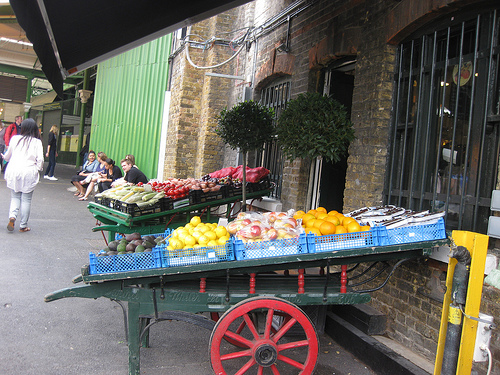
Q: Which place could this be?
A: It is a street.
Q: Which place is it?
A: It is a street.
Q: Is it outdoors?
A: Yes, it is outdoors.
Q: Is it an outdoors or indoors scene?
A: It is outdoors.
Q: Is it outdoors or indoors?
A: It is outdoors.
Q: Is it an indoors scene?
A: No, it is outdoors.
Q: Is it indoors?
A: No, it is outdoors.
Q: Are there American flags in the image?
A: No, there are no American flags.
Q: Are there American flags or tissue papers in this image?
A: No, there are no American flags or tissue papers.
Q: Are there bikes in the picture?
A: No, there are no bikes.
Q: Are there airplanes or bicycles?
A: No, there are no bicycles or airplanes.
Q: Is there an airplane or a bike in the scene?
A: No, there are no bikes or airplanes.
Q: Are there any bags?
A: No, there are no bags.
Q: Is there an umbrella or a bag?
A: No, there are no bags or umbrellas.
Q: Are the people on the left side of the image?
A: Yes, the people are on the left of the image.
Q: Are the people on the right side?
A: No, the people are on the left of the image.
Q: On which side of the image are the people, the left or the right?
A: The people are on the left of the image.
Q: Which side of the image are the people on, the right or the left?
A: The people are on the left of the image.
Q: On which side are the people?
A: The people are on the left of the image.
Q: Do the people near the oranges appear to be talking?
A: Yes, the people are talking.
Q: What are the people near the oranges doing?
A: The people are talking.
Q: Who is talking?
A: The people are talking.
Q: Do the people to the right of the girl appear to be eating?
A: No, the people are talking.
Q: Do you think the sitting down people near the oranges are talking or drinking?
A: The people are talking.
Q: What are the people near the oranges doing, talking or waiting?
A: The people are talking.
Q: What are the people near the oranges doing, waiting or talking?
A: The people are talking.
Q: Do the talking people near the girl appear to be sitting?
A: Yes, the people are sitting.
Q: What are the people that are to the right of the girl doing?
A: The people are sitting.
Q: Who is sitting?
A: The people are sitting.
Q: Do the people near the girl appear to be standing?
A: No, the people are sitting.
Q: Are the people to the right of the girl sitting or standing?
A: The people are sitting.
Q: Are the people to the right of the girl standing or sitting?
A: The people are sitting.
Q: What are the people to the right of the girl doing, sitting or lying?
A: The people are sitting.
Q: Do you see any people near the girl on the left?
A: Yes, there are people near the girl.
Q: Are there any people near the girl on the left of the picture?
A: Yes, there are people near the girl.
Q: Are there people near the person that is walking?
A: Yes, there are people near the girl.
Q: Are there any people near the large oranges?
A: Yes, there are people near the oranges.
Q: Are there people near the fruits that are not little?
A: Yes, there are people near the oranges.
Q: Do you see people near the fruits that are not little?
A: Yes, there are people near the oranges.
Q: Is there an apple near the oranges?
A: No, there are people near the oranges.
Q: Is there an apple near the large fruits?
A: No, there are people near the oranges.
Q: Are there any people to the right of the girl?
A: Yes, there are people to the right of the girl.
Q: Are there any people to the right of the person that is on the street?
A: Yes, there are people to the right of the girl.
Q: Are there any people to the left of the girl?
A: No, the people are to the right of the girl.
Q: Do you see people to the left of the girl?
A: No, the people are to the right of the girl.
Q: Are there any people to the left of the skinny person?
A: No, the people are to the right of the girl.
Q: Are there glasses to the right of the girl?
A: No, there are people to the right of the girl.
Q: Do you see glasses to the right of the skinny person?
A: No, there are people to the right of the girl.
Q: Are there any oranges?
A: Yes, there are oranges.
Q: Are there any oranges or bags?
A: Yes, there are oranges.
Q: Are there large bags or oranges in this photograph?
A: Yes, there are large oranges.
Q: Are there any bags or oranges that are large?
A: Yes, the oranges are large.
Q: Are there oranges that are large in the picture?
A: Yes, there are large oranges.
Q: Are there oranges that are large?
A: Yes, there are oranges that are large.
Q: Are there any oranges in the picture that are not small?
A: Yes, there are large oranges.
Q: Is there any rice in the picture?
A: No, there is no rice.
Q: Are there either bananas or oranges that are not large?
A: No, there are oranges but they are large.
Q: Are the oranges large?
A: Yes, the oranges are large.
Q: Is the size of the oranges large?
A: Yes, the oranges are large.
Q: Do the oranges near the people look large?
A: Yes, the oranges are large.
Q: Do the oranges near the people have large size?
A: Yes, the oranges are large.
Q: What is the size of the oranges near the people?
A: The oranges are large.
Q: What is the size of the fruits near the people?
A: The oranges are large.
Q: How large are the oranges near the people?
A: The oranges are large.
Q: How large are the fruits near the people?
A: The oranges are large.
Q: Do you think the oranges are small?
A: No, the oranges are large.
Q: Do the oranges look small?
A: No, the oranges are large.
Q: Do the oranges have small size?
A: No, the oranges are large.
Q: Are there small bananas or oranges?
A: No, there are oranges but they are large.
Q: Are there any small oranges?
A: No, there are oranges but they are large.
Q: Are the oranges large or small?
A: The oranges are large.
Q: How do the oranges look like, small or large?
A: The oranges are large.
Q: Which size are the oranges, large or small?
A: The oranges are large.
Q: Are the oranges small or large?
A: The oranges are large.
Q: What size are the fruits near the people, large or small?
A: The oranges are large.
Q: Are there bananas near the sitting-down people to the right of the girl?
A: No, there are oranges near the people.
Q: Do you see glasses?
A: No, there are no glasses.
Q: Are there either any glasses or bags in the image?
A: No, there are no glasses or bags.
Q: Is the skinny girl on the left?
A: Yes, the girl is on the left of the image.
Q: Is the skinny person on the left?
A: Yes, the girl is on the left of the image.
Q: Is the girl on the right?
A: No, the girl is on the left of the image.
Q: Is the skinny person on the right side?
A: No, the girl is on the left of the image.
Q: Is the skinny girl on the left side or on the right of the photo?
A: The girl is on the left of the image.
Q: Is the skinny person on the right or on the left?
A: The girl is on the left of the image.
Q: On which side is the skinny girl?
A: The girl is on the left of the image.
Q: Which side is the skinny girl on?
A: The girl is on the left of the image.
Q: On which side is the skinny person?
A: The girl is on the left of the image.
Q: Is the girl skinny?
A: Yes, the girl is skinny.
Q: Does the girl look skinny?
A: Yes, the girl is skinny.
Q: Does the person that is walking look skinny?
A: Yes, the girl is skinny.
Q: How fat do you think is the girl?
A: The girl is skinny.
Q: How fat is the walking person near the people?
A: The girl is skinny.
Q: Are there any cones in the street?
A: No, there is a girl in the street.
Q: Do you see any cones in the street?
A: No, there is a girl in the street.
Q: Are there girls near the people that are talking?
A: Yes, there is a girl near the people.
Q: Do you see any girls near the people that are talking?
A: Yes, there is a girl near the people.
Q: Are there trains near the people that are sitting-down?
A: No, there is a girl near the people.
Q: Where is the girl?
A: The girl is on the street.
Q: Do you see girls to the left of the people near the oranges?
A: Yes, there is a girl to the left of the people.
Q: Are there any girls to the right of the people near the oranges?
A: No, the girl is to the left of the people.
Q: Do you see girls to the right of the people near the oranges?
A: No, the girl is to the left of the people.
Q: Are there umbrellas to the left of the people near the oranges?
A: No, there is a girl to the left of the people.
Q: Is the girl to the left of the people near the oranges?
A: Yes, the girl is to the left of the people.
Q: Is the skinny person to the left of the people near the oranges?
A: Yes, the girl is to the left of the people.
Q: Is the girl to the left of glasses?
A: No, the girl is to the left of the people.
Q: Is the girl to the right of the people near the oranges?
A: No, the girl is to the left of the people.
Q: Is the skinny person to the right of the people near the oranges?
A: No, the girl is to the left of the people.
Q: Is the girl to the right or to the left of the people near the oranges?
A: The girl is to the left of the people.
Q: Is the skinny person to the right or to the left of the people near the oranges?
A: The girl is to the left of the people.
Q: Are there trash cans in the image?
A: No, there are no trash cans.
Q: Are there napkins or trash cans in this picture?
A: No, there are no trash cans or napkins.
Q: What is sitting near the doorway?
A: The plant is sitting near the doorway.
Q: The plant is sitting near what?
A: The plant is sitting by the doorway.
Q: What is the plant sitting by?
A: The plant is sitting by the doorway.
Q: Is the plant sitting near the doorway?
A: Yes, the plant is sitting near the doorway.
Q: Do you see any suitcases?
A: No, there are no suitcases.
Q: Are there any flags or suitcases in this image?
A: No, there are no suitcases or flags.